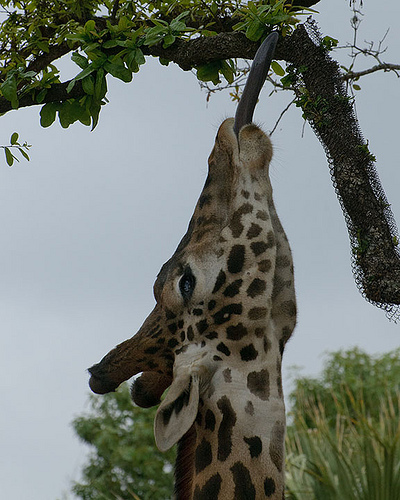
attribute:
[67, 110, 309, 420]
head — giraffe's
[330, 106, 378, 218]
mesh — wire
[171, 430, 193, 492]
hair — brown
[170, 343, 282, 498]
back — giraffe's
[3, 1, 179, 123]
leaves — green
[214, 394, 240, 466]
spot — brown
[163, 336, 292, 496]
neck — giraffe's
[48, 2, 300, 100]
leaves — green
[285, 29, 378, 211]
mesh — wire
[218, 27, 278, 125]
tongue — long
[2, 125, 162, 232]
sky — blue, daytime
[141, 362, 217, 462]
ear — pointed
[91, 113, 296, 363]
head — giraffe, pointed upward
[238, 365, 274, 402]
spot — brown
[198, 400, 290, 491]
fur — beige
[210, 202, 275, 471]
spots — dark brown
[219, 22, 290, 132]
vegetable — large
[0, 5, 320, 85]
leaves — green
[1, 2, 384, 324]
large tree — branch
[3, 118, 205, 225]
sky — clear, blue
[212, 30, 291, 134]
tongue — long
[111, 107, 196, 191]
patch — cloudless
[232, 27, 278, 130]
tongue — black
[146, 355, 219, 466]
ear — small, gray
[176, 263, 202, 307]
eye — small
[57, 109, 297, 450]
head — extended, giraffe's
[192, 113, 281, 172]
mouth — giraffe's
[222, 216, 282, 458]
spots — brown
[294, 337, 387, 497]
plants — tall, light green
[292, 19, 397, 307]
back — black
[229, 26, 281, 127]
tongue — out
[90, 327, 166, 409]
giraffe's horn — Short, brown